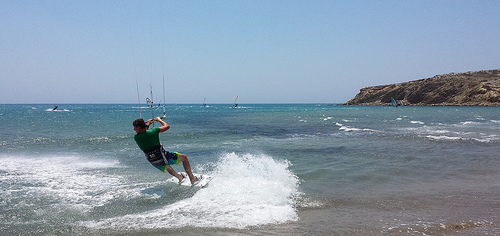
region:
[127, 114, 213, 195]
wind surfer leaning backwards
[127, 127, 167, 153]
green shirt on surfer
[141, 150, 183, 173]
men's green and black shorts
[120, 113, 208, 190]
adult white male surfer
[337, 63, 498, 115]
rocky point in background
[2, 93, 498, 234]
calm blue ocean water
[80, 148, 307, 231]
splashing white wave top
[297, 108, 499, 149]
distant cresting ocean waves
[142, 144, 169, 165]
safety harness on surfer's waist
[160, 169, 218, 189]
white wave board on water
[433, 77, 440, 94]
edge of a rock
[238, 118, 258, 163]
edge of a wave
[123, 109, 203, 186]
man on a board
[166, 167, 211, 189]
white board on the water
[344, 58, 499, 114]
brown cliff near the water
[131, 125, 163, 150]
man's green colored shirt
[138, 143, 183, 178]
man's multicolored swim trunks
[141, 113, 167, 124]
bar in a man's hand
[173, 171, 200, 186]
both feet on the board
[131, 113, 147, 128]
man's dark colored hair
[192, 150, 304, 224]
white splashing waves of water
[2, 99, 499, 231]
water in the ocean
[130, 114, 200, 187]
The person is parasailing.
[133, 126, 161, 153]
The shirt is green.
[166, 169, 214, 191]
The platform is white.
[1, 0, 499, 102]
The sky is a hazy light blue.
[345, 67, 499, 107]
The cliff is brown and gray.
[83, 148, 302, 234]
The person is creating a wave.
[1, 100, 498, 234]
The water is turquoise.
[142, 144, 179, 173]
The person is wearing shorts.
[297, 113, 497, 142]
The water has some small waves.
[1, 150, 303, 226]
The waves are very bright white.